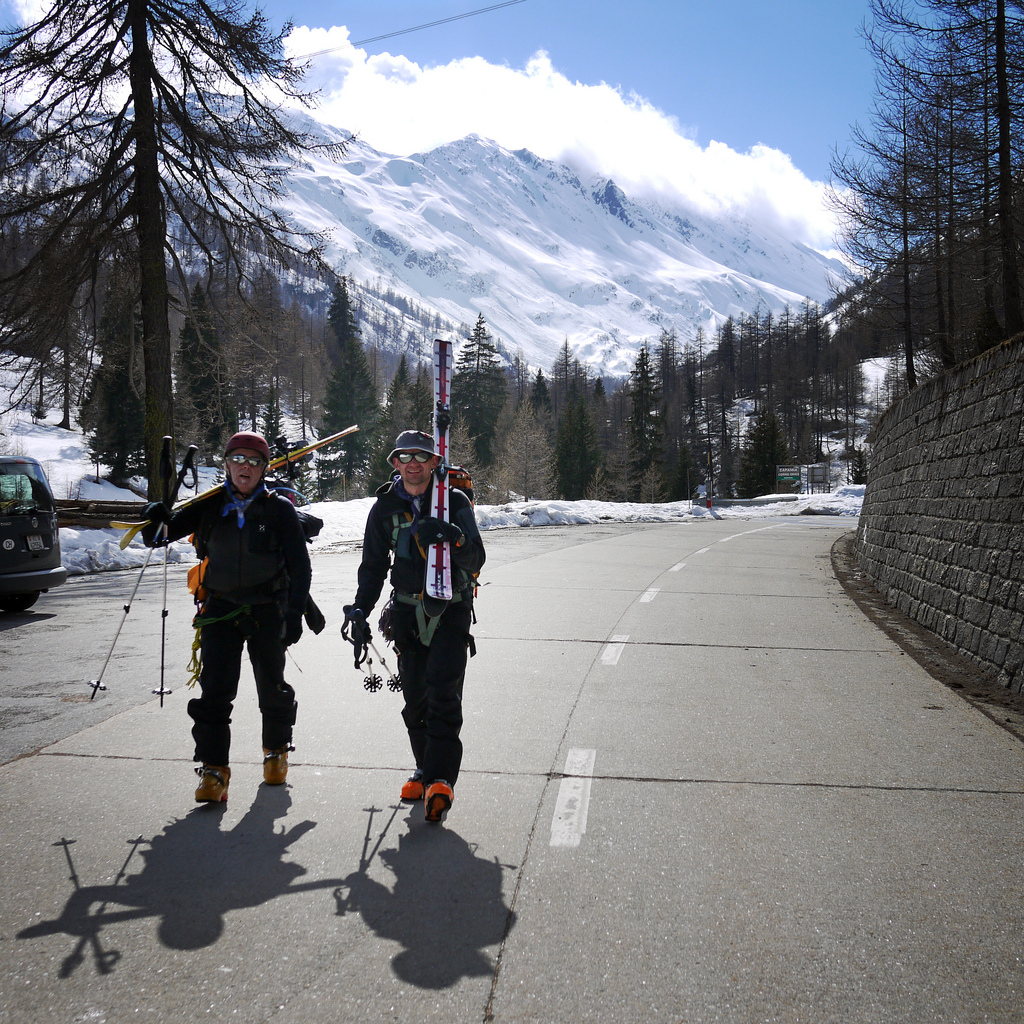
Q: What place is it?
A: It is a street.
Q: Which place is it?
A: It is a street.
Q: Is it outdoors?
A: Yes, it is outdoors.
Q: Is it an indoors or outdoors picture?
A: It is outdoors.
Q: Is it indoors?
A: No, it is outdoors.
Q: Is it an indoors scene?
A: No, it is outdoors.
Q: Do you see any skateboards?
A: No, there are no skateboards.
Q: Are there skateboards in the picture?
A: No, there are no skateboards.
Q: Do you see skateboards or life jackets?
A: No, there are no skateboards or life jackets.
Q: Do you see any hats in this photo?
A: Yes, there is a hat.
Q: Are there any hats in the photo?
A: Yes, there is a hat.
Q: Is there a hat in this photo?
A: Yes, there is a hat.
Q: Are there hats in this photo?
A: Yes, there is a hat.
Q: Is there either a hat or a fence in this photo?
A: Yes, there is a hat.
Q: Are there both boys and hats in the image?
A: No, there is a hat but no boys.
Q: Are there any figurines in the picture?
A: No, there are no figurines.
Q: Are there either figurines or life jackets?
A: No, there are no figurines or life jackets.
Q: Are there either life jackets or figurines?
A: No, there are no figurines or life jackets.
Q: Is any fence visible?
A: No, there are no fences.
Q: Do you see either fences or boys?
A: No, there are no fences or boys.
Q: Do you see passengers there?
A: No, there are no passengers.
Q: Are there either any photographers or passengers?
A: No, there are no passengers or photographers.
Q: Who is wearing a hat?
A: The man is wearing a hat.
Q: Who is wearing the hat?
A: The man is wearing a hat.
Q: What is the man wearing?
A: The man is wearing a hat.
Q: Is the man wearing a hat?
A: Yes, the man is wearing a hat.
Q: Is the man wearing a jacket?
A: No, the man is wearing a hat.